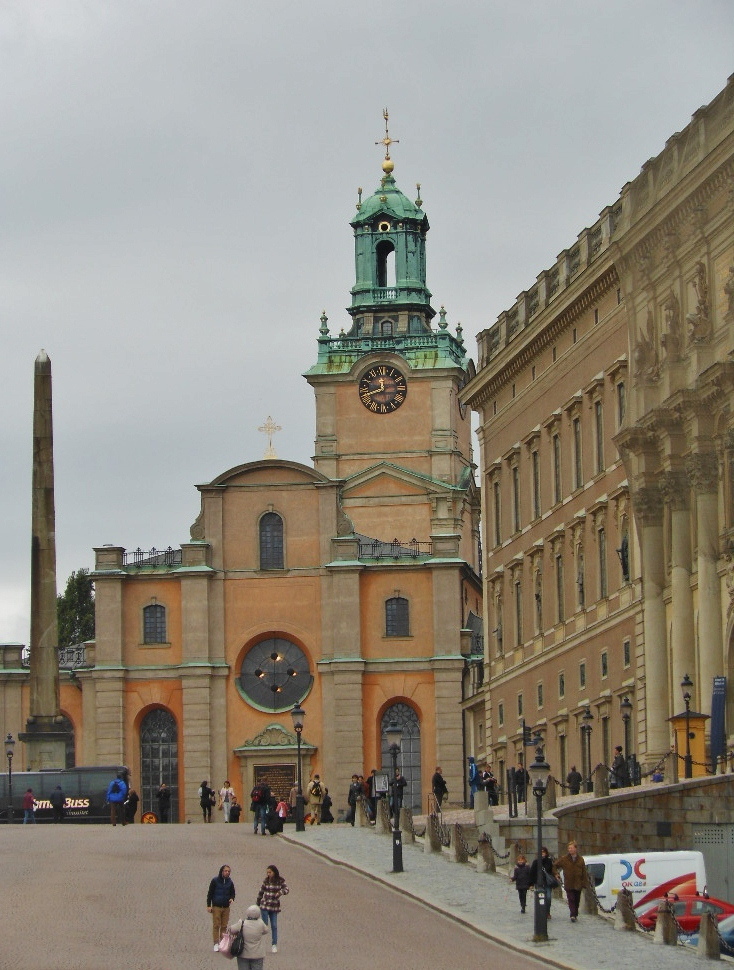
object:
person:
[348, 774, 365, 826]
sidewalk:
[277, 826, 734, 970]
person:
[552, 840, 587, 922]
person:
[529, 846, 553, 920]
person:
[432, 765, 448, 813]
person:
[389, 767, 407, 818]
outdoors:
[0, 4, 734, 970]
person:
[207, 865, 236, 952]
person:
[231, 905, 269, 970]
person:
[509, 854, 531, 913]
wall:
[223, 466, 323, 823]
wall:
[223, 466, 321, 570]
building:
[190, 416, 355, 580]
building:
[455, 70, 734, 806]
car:
[634, 885, 734, 930]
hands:
[363, 378, 385, 397]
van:
[560, 851, 706, 911]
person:
[256, 865, 288, 954]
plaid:
[256, 876, 289, 912]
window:
[259, 512, 284, 569]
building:
[0, 107, 483, 823]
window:
[386, 597, 410, 636]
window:
[143, 605, 166, 644]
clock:
[359, 365, 407, 415]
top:
[301, 106, 476, 376]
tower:
[301, 98, 485, 823]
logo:
[620, 859, 646, 881]